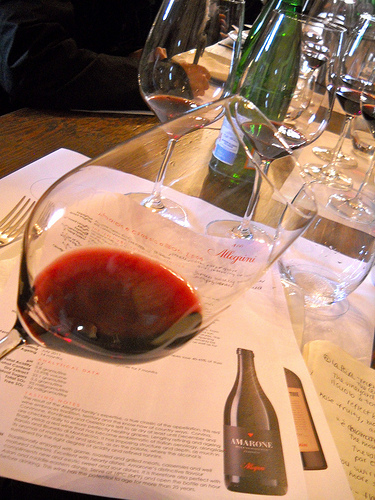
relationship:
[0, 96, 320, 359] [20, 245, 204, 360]
glasses with wine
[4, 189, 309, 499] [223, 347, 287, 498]
information about bottle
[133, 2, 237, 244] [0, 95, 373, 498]
glasses on table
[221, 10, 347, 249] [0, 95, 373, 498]
glasses on table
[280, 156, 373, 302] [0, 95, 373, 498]
glasses on table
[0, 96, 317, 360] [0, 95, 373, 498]
glasses on table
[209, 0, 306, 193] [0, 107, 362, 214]
bottle on table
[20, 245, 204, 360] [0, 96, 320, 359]
wine in glasses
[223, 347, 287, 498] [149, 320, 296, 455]
bottle on paper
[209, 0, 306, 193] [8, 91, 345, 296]
bottle on table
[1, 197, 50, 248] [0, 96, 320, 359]
fork next to glasses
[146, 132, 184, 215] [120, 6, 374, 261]
stems on glasses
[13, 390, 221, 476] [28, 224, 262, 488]
writing on paper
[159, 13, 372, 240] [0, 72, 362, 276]
glasses on table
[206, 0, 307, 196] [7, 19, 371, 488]
bottle on table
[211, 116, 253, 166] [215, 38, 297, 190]
label on bottle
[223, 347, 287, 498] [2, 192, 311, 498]
bottle on page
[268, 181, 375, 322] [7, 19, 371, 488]
glasses on table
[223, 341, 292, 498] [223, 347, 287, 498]
bottle of bottle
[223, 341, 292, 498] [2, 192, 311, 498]
bottle on page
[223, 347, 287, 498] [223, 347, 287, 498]
bottle of bottle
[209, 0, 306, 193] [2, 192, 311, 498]
bottle on page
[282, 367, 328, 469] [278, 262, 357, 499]
bottle on page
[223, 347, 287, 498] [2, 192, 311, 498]
bottle of wine on page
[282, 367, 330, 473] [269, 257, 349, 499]
bottle on page